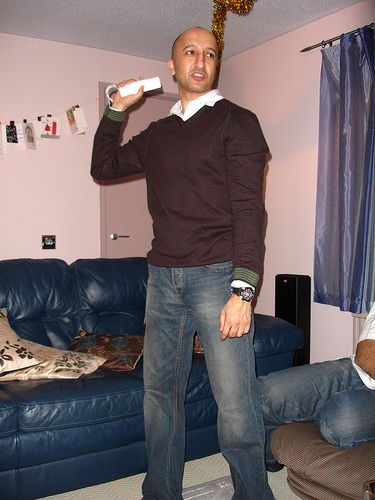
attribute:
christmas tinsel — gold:
[211, 0, 258, 55]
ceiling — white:
[0, 0, 365, 63]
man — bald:
[89, 25, 271, 499]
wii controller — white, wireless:
[105, 75, 163, 104]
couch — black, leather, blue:
[0, 255, 306, 500]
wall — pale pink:
[0, 30, 179, 264]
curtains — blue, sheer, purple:
[310, 22, 373, 314]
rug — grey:
[181, 473, 236, 499]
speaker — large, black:
[276, 273, 311, 367]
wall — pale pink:
[217, 0, 375, 366]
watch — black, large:
[230, 285, 255, 301]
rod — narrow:
[299, 21, 373, 53]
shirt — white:
[167, 89, 223, 123]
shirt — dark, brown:
[91, 96, 270, 288]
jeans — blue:
[141, 261, 277, 499]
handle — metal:
[110, 232, 131, 242]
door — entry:
[97, 80, 181, 259]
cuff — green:
[232, 267, 259, 287]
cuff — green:
[104, 105, 126, 123]